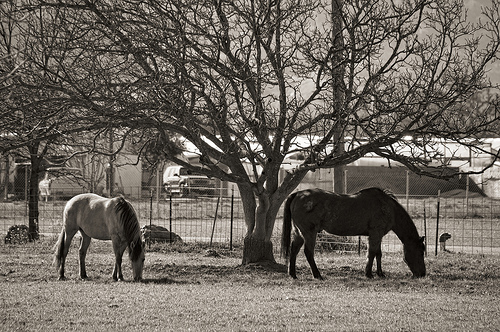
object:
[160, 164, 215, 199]
vehicle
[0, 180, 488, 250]
fence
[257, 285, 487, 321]
grass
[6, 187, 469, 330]
meadow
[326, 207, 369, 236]
stomach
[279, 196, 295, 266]
tail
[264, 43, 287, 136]
branch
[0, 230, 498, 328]
field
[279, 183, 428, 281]
horse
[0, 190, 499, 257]
fence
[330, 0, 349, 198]
pole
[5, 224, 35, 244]
bush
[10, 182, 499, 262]
fence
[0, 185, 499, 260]
wire fence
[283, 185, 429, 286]
black horse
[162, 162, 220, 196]
suv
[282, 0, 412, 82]
ground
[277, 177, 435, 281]
remote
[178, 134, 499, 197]
snow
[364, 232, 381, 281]
leg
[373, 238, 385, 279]
leg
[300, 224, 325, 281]
leg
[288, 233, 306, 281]
leg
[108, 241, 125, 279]
leg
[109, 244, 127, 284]
leg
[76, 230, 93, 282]
leg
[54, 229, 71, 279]
leg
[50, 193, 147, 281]
horse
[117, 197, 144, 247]
mane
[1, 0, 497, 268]
tree